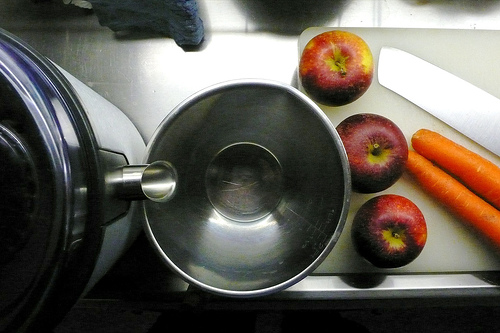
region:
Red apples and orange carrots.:
[269, 7, 499, 288]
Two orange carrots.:
[410, 123, 498, 265]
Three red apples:
[298, 31, 438, 293]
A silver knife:
[367, 32, 494, 153]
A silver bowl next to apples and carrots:
[121, 58, 352, 329]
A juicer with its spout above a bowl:
[0, 25, 191, 322]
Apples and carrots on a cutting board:
[289, 25, 498, 304]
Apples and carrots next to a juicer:
[281, 28, 495, 287]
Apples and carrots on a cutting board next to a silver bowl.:
[301, 17, 498, 307]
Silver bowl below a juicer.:
[130, 75, 367, 330]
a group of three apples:
[298, 30, 428, 269]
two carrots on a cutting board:
[408, 127, 498, 258]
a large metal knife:
[376, 43, 498, 155]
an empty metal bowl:
[136, 75, 351, 297]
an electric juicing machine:
[0, 25, 178, 331]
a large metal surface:
[0, 0, 499, 301]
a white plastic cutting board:
[298, 25, 499, 275]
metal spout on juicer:
[121, 159, 175, 205]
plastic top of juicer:
[0, 22, 87, 330]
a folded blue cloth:
[99, 0, 204, 46]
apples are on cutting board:
[303, 32, 428, 267]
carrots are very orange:
[408, 125, 499, 240]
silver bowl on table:
[146, 79, 353, 294]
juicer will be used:
[0, 30, 170, 310]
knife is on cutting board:
[376, 45, 498, 152]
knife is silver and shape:
[378, 45, 498, 153]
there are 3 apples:
[303, 28, 430, 265]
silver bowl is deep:
[144, 79, 352, 293]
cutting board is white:
[300, 26, 498, 274]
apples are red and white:
[303, 32, 428, 264]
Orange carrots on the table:
[432, 113, 486, 265]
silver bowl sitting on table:
[183, 81, 278, 308]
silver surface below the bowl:
[85, 32, 269, 119]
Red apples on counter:
[309, 55, 414, 252]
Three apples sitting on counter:
[325, 45, 418, 288]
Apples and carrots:
[303, 61, 493, 216]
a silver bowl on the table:
[173, 45, 275, 304]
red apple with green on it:
[311, 48, 381, 93]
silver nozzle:
[98, 156, 173, 218]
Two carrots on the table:
[408, 137, 498, 234]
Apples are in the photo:
[258, 35, 492, 299]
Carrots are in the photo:
[361, 96, 496, 267]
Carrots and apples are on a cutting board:
[276, 12, 481, 283]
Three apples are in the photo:
[267, 4, 447, 285]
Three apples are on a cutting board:
[298, 24, 487, 306]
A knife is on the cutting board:
[299, 21, 486, 291]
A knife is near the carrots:
[290, 29, 466, 296]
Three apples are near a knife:
[305, 25, 496, 270]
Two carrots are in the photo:
[383, 59, 498, 283]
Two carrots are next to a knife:
[336, 29, 498, 221]